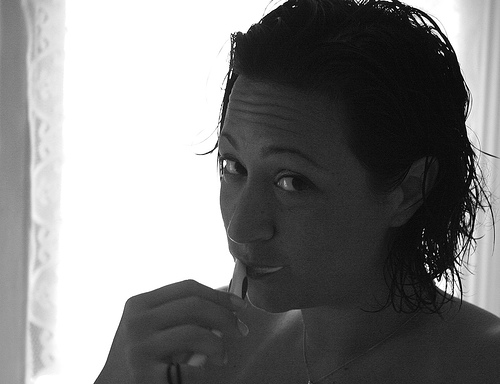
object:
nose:
[226, 187, 276, 246]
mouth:
[228, 250, 290, 282]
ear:
[389, 154, 441, 231]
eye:
[268, 168, 322, 196]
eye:
[215, 150, 250, 183]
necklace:
[294, 304, 433, 384]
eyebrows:
[218, 131, 331, 176]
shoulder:
[404, 293, 499, 384]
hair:
[190, 0, 497, 324]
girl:
[86, 0, 499, 384]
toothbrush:
[186, 257, 251, 368]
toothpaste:
[243, 263, 283, 276]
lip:
[228, 251, 289, 282]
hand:
[93, 277, 252, 384]